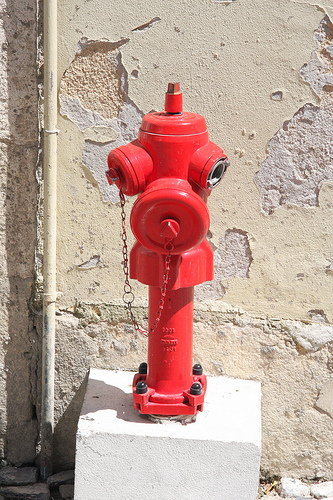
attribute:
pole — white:
[27, 8, 61, 184]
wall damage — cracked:
[267, 88, 283, 103]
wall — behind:
[56, 0, 332, 483]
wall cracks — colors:
[253, 89, 321, 220]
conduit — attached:
[42, 1, 58, 474]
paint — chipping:
[254, 133, 301, 213]